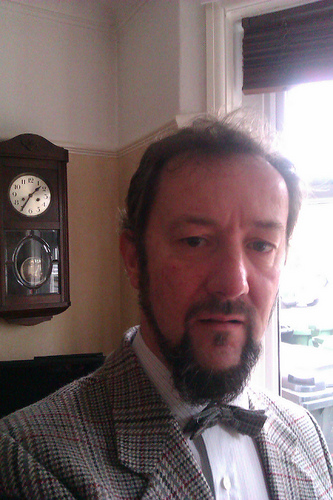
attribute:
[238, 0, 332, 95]
curtains — brown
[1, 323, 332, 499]
suit — red, gray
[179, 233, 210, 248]
eye — brown 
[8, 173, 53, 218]
clock — brown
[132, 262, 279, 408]
beard — well groomed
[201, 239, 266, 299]
nose — man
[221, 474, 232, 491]
button — white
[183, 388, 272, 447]
tie — bow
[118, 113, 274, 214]
hair — brown , short 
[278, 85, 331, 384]
sunlight — bright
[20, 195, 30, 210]
hands — black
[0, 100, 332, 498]
man — balding, concerned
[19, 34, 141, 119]
wall — white, tan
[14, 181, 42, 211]
face — Silver 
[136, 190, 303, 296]
eye — man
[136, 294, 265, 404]
facial hair — dark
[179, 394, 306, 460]
bowtie — drooping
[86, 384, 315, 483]
jacket — suit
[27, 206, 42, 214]
numbers — black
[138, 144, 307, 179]
hair — short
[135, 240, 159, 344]
burns — side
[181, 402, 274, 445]
tie — bow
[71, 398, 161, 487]
jacket — plaid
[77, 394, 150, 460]
jacket — multi colored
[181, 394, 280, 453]
tie — bow